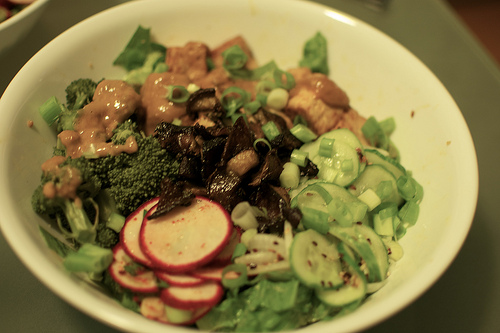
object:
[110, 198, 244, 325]
slices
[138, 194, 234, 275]
radish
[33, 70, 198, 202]
vinaigrette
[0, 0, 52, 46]
bowl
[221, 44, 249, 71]
green onion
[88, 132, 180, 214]
broccoli head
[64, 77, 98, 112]
broccoli head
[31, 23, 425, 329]
salad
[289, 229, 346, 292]
cucumber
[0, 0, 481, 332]
bowl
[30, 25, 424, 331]
food